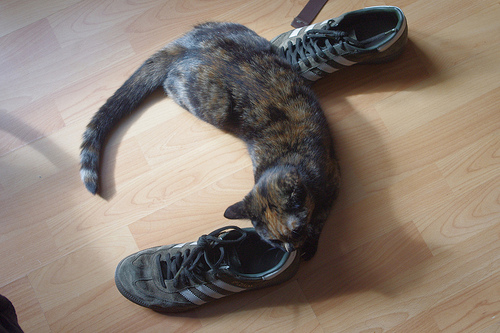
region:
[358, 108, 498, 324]
The hardwood floor is light brown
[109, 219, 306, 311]
The shoe is on the floor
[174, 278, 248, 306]
The side of the show has white stripes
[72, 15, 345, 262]
The cat is on the floor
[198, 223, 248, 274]
The shoe string is gray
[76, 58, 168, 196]
The tail of the cat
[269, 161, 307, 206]
The ear of the cat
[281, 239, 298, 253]
The nose of the cat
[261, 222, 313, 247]
The eyes of the cat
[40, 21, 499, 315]
The cat is playing with the shoe on the floor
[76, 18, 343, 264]
A cat on the floor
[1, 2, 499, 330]
The floor is made of wood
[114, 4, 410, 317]
A pair of sneakers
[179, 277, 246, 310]
White stripes on a sneaker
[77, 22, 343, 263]
The cat is brown and black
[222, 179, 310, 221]
Two ears on a cat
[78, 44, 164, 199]
Tail of the cat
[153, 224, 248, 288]
Black shoelaces on a sneaker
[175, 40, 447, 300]
Shadows on the floor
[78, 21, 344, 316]
The cat is biting a shoe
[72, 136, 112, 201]
end of cat tail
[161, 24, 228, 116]
rear end of cat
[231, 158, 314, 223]
top of cat head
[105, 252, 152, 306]
top of grey sneaker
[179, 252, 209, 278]
shoe strings on sneakers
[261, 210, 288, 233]
gold patch on cats head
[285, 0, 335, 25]
purple strap on floor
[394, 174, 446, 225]
wood pattern on floor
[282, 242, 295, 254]
grey nose on cat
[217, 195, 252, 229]
left ear on cat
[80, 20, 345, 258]
A black and brown cat.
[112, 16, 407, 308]
Black shoes with white stripes.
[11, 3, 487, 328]
Black and white shoes on a wooden floor.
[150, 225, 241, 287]
Black shoe strings on the shoe.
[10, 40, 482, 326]
Different shades of brown on a wood floor.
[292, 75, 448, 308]
The cat's shadow on the wood floor.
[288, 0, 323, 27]
The edge of a brown belt.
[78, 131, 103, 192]
Stripes on the end of the cat's tail.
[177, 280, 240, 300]
White strpes on the side of the shoe.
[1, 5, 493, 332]
Thin lines between wooden planks.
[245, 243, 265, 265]
The inside of a shoe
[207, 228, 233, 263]
Shoe lace tied in a bow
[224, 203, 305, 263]
A cat biting a shoe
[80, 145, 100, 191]
The tip of a tail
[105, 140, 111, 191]
Shadow cast by the tail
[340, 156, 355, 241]
The cat's shadow on the floor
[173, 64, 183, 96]
Light reflecting on the fur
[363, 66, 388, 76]
Shadow from the shoe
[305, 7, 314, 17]
A strap on the floor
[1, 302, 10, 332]
A protruding black object